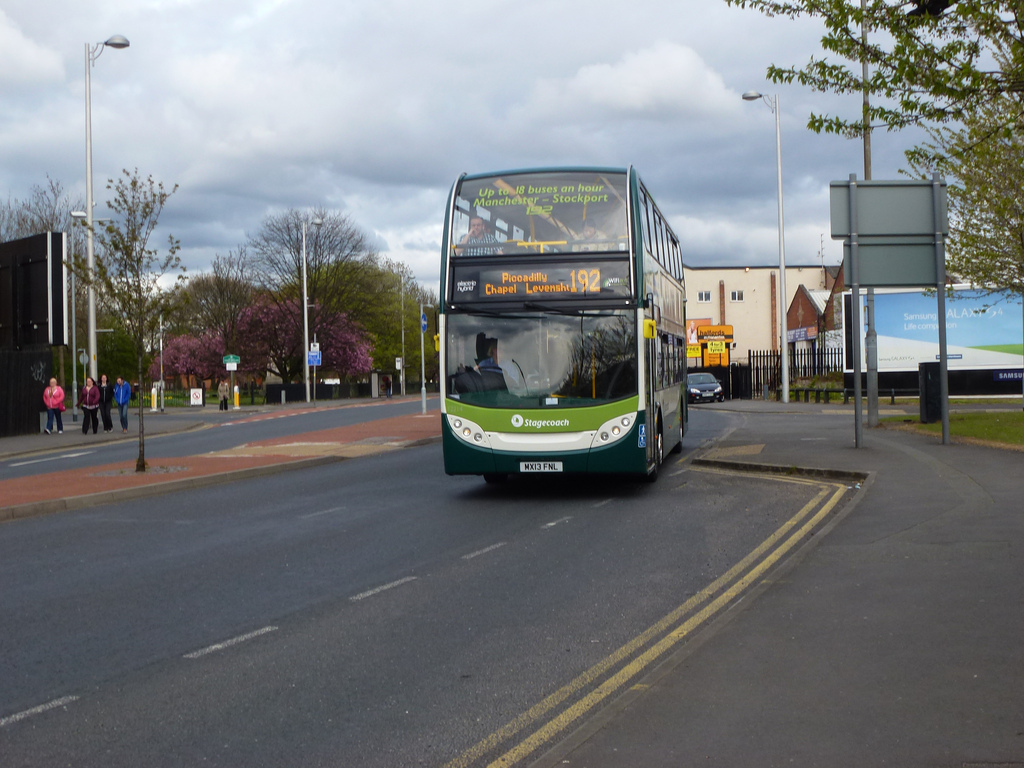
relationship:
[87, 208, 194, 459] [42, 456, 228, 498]
tree in divider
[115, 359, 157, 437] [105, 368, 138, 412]
pedestrian in jacket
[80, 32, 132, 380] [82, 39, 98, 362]
street light on pole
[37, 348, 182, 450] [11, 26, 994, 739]
people are enjoying outdoors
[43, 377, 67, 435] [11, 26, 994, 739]
people are enjoying outdoors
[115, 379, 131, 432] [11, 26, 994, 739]
pedestrian are enjoying outdoors